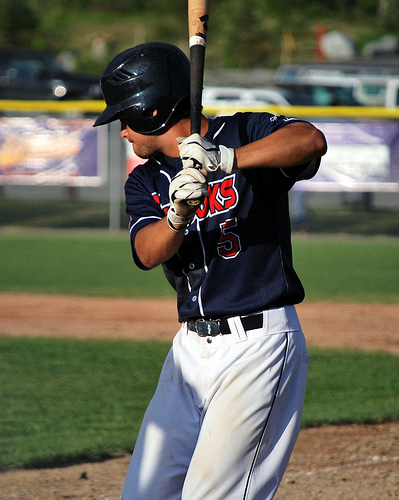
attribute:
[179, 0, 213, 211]
bat — wood, brown, black, wooden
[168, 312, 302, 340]
belt — black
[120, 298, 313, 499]
pants — white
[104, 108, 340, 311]
shirt — navy blue, black, blue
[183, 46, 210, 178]
handle — black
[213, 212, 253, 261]
number — five, red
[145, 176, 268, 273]
lettering — red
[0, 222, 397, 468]
grass — green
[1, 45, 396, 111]
cars — parked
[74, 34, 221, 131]
helmet — black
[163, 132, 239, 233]
gloves — white, black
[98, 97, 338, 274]
skin — light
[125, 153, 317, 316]
trim — white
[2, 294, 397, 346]
clay — red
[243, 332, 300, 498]
trim — black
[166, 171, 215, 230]
glove — clenched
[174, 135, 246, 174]
glove — clenched